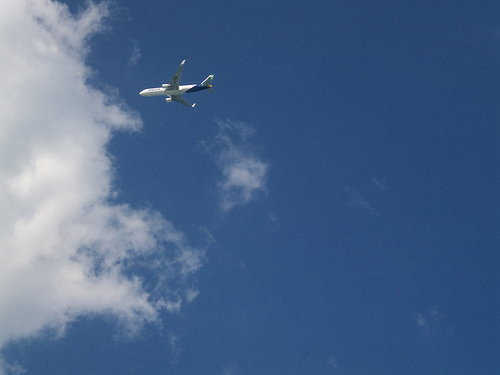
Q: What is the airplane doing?
A: Flying.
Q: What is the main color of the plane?
A: White.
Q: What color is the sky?
A: Blue.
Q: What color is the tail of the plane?
A: Blue.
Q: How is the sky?
A: Cloudy.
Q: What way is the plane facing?
A: Left.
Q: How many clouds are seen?
A: Two.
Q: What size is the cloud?
A: Large.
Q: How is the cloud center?
A: Dense.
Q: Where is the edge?
A: On cloud.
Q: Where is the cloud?
A: Front of plane.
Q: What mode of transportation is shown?
A: Plane.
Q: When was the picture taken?
A: Daytime.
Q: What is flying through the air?
A: An airplane.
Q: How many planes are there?
A: One.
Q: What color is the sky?
A: Blue.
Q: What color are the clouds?
A: White.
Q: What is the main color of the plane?
A: White.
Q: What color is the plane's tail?
A: Blue.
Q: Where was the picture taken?
A: In the sky.